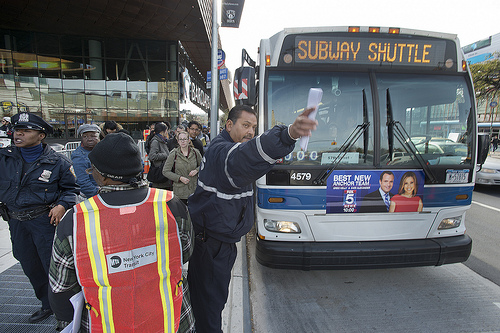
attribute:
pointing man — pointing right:
[188, 98, 319, 331]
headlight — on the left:
[431, 209, 466, 244]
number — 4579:
[289, 171, 311, 181]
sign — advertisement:
[327, 164, 432, 213]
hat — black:
[92, 131, 152, 178]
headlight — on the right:
[262, 218, 301, 233]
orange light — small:
[346, 26, 364, 34]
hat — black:
[87, 125, 150, 180]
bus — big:
[238, 16, 494, 266]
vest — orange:
[71, 205, 195, 332]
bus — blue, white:
[253, 23, 490, 265]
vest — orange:
[57, 170, 224, 316]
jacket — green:
[165, 147, 197, 195]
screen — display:
[289, 35, 442, 70]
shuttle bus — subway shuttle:
[231, 20, 478, 272]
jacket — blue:
[182, 124, 301, 239]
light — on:
[262, 217, 300, 239]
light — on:
[436, 214, 463, 230]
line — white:
[470, 199, 499, 218]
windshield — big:
[264, 69, 459, 179]